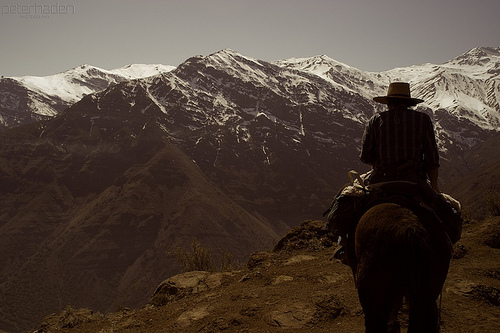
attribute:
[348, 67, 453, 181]
man — riding, looking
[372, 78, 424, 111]
cap — snow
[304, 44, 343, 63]
snow — white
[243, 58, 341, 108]
mountain — brown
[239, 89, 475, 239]
scene — cowboy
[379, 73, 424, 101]
hat — cowboy, ten, gallon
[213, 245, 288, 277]
terrain — rocky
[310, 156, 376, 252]
bag — saddle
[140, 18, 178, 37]
sky — clear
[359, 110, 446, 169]
shirt — plaid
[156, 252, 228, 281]
plant — green